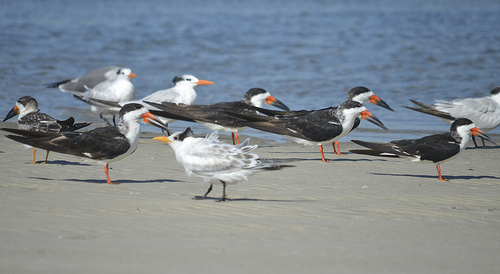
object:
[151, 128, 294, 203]
bird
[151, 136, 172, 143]
beak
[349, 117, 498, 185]
birds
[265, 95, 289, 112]
beaks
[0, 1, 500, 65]
water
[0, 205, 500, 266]
sand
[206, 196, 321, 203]
shadow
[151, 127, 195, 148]
head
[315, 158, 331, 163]
feet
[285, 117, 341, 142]
wings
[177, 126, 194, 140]
feathers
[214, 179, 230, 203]
legs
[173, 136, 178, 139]
eye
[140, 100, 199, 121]
feathers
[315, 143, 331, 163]
legs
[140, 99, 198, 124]
tail